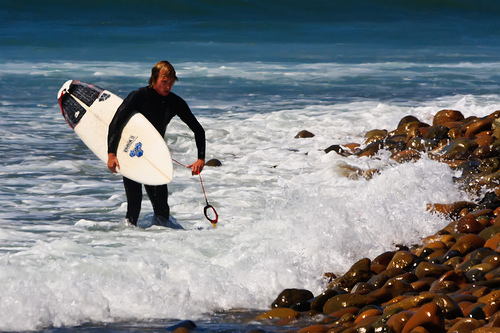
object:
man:
[107, 61, 206, 225]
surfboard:
[54, 80, 174, 185]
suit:
[106, 88, 206, 226]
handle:
[203, 205, 219, 225]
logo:
[129, 142, 144, 158]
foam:
[0, 92, 497, 332]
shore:
[270, 109, 499, 332]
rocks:
[257, 110, 500, 333]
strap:
[172, 158, 194, 171]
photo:
[2, 1, 498, 333]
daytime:
[0, 2, 498, 332]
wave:
[0, 155, 468, 332]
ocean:
[0, 2, 500, 333]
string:
[199, 173, 209, 207]